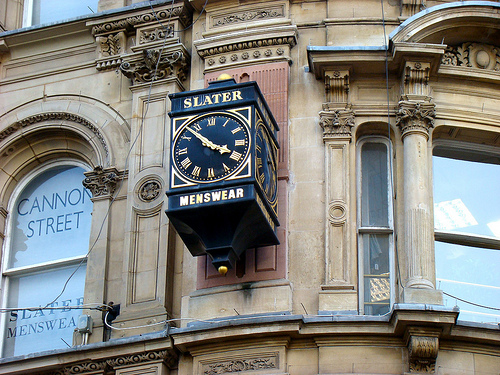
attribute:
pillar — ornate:
[1, 0, 498, 373]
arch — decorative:
[385, 1, 499, 72]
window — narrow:
[358, 131, 393, 316]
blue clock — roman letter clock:
[164, 73, 279, 273]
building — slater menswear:
[74, 53, 452, 315]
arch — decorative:
[5, 97, 121, 338]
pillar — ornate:
[70, 154, 116, 368]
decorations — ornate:
[202, 8, 289, 65]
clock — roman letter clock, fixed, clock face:
[165, 75, 278, 275]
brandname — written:
[164, 83, 264, 109]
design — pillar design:
[375, 44, 447, 367]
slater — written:
[174, 82, 262, 112]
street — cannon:
[0, 85, 170, 373]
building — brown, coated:
[7, 19, 481, 372]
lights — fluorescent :
[440, 161, 486, 279]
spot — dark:
[229, 273, 262, 311]